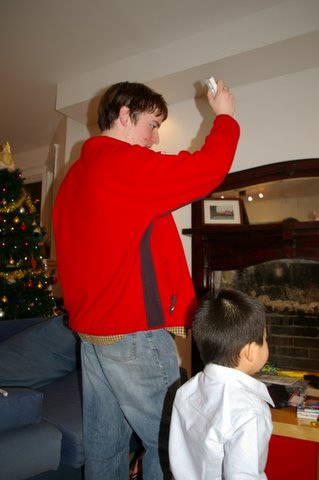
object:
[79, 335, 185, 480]
jeans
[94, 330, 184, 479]
legs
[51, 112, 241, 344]
jacket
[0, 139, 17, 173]
angel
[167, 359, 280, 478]
collared shirt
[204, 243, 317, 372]
fireplace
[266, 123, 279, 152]
ground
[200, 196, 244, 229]
picture frame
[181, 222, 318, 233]
shelf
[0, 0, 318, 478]
room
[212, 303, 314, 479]
table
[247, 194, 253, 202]
lights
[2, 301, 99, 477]
couch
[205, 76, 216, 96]
controller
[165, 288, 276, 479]
boy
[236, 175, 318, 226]
mirror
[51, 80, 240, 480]
man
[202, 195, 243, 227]
picture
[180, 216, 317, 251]
mantlepiece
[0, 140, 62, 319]
christmas tree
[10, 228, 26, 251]
ornaments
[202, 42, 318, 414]
video game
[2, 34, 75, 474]
background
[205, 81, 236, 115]
hand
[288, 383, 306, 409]
items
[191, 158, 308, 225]
mantelpiece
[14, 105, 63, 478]
livingroom